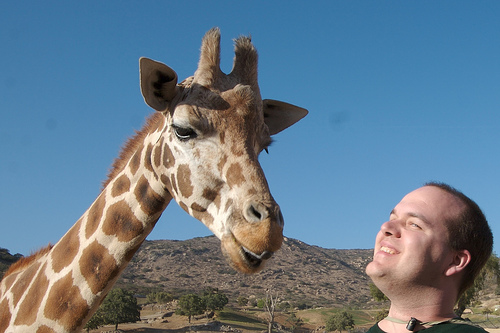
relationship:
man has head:
[359, 150, 491, 332] [387, 174, 485, 291]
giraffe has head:
[26, 46, 296, 319] [119, 50, 306, 286]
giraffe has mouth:
[26, 46, 296, 319] [231, 232, 287, 276]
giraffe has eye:
[26, 46, 296, 319] [158, 108, 205, 151]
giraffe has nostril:
[26, 46, 296, 319] [245, 186, 276, 226]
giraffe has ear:
[26, 46, 296, 319] [132, 46, 208, 158]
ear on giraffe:
[132, 46, 208, 158] [26, 46, 296, 319]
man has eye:
[359, 150, 491, 332] [397, 214, 416, 230]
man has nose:
[359, 150, 491, 332] [372, 213, 458, 270]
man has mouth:
[359, 150, 491, 332] [373, 241, 403, 259]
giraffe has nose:
[26, 46, 296, 319] [372, 213, 458, 270]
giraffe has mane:
[26, 46, 296, 319] [109, 111, 170, 181]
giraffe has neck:
[26, 46, 296, 319] [10, 168, 152, 307]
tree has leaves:
[179, 266, 208, 331] [170, 291, 191, 317]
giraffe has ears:
[26, 46, 296, 319] [131, 51, 318, 138]